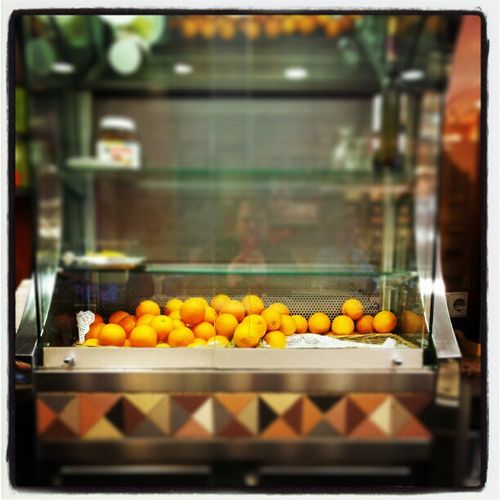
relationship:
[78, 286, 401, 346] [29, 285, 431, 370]
oranges in rack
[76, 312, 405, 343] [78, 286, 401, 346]
paper under oranges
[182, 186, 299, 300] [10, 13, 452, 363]
reflection in glass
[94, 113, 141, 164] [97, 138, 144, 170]
bottle has label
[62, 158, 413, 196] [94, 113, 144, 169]
top shelf has bottle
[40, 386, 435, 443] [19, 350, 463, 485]
design in bottom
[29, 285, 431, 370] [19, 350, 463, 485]
rack has bottom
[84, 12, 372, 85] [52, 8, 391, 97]
reflection in glass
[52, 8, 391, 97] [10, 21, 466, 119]
glass at top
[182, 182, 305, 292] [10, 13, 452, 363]
man in glass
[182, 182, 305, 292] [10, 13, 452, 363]
man reflected in glass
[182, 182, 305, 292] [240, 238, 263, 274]
man has mobile phone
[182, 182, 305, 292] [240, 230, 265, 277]
man uses cellphone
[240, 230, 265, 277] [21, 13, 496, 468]
cellphone captures picture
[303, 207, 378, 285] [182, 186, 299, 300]
person captured in reflection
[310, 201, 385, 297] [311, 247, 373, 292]
individual wears shirt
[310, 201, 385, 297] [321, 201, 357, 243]
individual with hair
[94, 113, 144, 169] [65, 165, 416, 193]
bottle on shelf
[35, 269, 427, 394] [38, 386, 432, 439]
shelf has strip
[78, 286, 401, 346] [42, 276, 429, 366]
oranges in bin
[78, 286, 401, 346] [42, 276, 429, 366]
oranges stacked in bin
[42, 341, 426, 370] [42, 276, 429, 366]
piece on bin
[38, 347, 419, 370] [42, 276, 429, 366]
item on bin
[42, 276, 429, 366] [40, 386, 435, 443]
bin has design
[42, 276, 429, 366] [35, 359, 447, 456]
bin has front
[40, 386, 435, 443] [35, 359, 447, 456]
design on front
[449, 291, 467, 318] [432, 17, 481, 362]
knob on wall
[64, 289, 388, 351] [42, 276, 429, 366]
basket in bin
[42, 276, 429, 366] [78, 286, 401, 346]
bin with oranges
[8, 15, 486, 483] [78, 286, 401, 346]
cabinet with oranges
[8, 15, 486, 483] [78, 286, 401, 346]
cabinet filled with oranges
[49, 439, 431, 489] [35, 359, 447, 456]
door on front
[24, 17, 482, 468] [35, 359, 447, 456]
case has front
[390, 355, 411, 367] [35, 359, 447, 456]
knob on front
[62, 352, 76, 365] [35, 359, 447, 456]
knob on front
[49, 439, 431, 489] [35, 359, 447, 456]
door has front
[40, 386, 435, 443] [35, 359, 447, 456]
shapes on front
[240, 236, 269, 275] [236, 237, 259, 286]
man holding cup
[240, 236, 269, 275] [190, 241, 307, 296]
man wearing clothing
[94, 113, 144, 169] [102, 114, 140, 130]
bottle with lid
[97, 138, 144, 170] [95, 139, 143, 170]
label with label